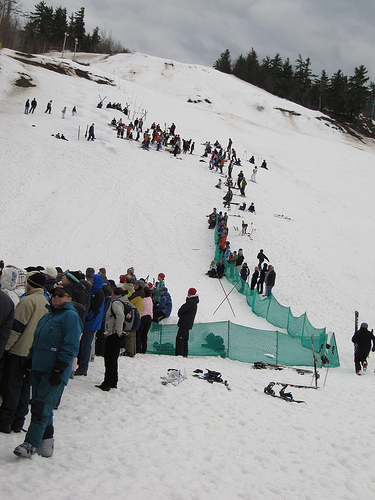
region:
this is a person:
[11, 286, 74, 484]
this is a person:
[172, 282, 200, 376]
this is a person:
[339, 315, 370, 365]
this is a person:
[268, 264, 276, 304]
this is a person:
[101, 285, 133, 402]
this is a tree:
[219, 42, 232, 75]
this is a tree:
[74, 4, 91, 57]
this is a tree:
[294, 60, 309, 107]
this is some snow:
[63, 359, 363, 495]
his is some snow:
[12, 50, 369, 255]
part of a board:
[262, 370, 291, 420]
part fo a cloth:
[204, 351, 236, 398]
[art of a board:
[275, 397, 295, 444]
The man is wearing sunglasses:
[52, 291, 67, 297]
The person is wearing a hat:
[187, 288, 196, 296]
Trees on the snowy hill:
[3, 2, 126, 52]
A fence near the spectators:
[148, 218, 338, 368]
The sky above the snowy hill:
[0, 0, 373, 87]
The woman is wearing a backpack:
[112, 299, 139, 331]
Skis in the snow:
[273, 379, 320, 390]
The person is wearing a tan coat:
[5, 289, 47, 354]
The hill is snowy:
[0, 47, 371, 499]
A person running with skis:
[352, 311, 374, 372]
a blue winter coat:
[27, 303, 79, 372]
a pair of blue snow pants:
[25, 374, 63, 446]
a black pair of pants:
[102, 336, 120, 383]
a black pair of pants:
[174, 325, 190, 355]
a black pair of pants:
[353, 346, 369, 369]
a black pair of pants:
[137, 316, 150, 350]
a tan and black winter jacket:
[6, 290, 49, 356]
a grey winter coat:
[105, 294, 128, 336]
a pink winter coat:
[141, 297, 153, 319]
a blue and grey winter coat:
[158, 292, 173, 315]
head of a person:
[41, 279, 81, 311]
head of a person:
[15, 264, 53, 290]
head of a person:
[94, 280, 126, 305]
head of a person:
[174, 278, 211, 311]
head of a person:
[349, 316, 369, 342]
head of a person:
[259, 256, 275, 279]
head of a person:
[152, 263, 170, 281]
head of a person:
[123, 257, 144, 277]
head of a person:
[103, 278, 142, 302]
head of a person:
[94, 261, 130, 279]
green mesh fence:
[104, 213, 342, 368]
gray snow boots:
[4, 435, 54, 462]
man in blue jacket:
[81, 274, 102, 369]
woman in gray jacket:
[100, 280, 141, 396]